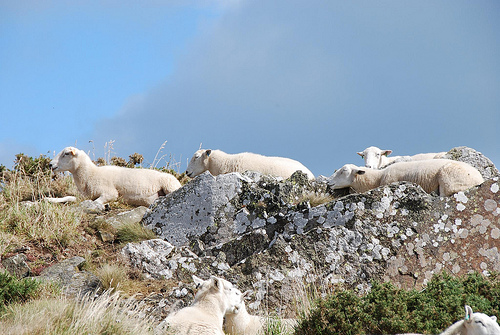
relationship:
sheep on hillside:
[56, 127, 473, 332] [0, 156, 496, 333]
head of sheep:
[186, 150, 213, 182] [183, 146, 316, 194]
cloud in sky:
[0, 0, 500, 177] [0, 0, 498, 173]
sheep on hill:
[49, 145, 185, 211] [0, 143, 498, 333]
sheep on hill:
[184, 147, 316, 184] [0, 143, 498, 333]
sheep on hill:
[327, 159, 484, 199] [0, 143, 498, 333]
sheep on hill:
[356, 145, 449, 169] [0, 143, 498, 333]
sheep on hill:
[153, 274, 242, 335] [0, 143, 498, 333]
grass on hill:
[5, 206, 91, 247] [0, 146, 500, 335]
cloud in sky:
[53, 1, 499, 177] [0, 0, 498, 173]